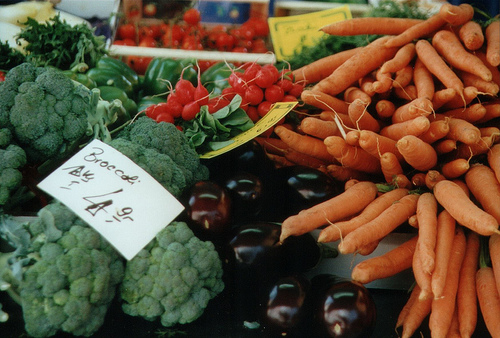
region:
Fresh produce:
[2, 29, 494, 295]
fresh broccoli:
[4, 75, 207, 323]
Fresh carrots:
[309, 24, 499, 239]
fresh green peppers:
[89, 53, 185, 98]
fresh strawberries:
[117, 0, 266, 54]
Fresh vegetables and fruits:
[4, 3, 489, 334]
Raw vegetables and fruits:
[8, 0, 494, 337]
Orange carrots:
[325, 18, 496, 336]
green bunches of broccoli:
[15, 63, 225, 316]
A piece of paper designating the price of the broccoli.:
[29, 120, 199, 275]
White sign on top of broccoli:
[37, 135, 184, 263]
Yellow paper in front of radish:
[199, 92, 301, 167]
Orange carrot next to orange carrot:
[435, 179, 499, 236]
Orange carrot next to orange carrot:
[414, 190, 437, 275]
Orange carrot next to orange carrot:
[270, 179, 379, 243]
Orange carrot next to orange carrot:
[376, 153, 401, 183]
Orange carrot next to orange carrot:
[312, 31, 402, 97]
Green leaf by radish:
[207, 105, 231, 118]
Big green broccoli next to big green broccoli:
[122, 224, 226, 326]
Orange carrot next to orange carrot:
[321, 134, 378, 174]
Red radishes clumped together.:
[146, 58, 310, 122]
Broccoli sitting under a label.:
[0, 62, 227, 330]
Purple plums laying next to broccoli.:
[184, 166, 375, 333]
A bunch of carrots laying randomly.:
[253, 6, 498, 336]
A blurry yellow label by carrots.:
[267, 8, 361, 55]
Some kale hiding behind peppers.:
[16, 10, 107, 80]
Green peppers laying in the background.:
[64, 57, 261, 112]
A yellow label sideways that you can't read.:
[193, 98, 299, 160]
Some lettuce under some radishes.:
[187, 92, 258, 150]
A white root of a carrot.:
[314, 95, 346, 136]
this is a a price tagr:
[27, 140, 163, 253]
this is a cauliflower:
[117, 232, 217, 327]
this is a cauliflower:
[0, 211, 126, 334]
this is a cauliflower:
[92, 115, 192, 196]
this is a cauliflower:
[10, 65, 91, 150]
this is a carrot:
[406, 175, 438, 293]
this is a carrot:
[423, 156, 489, 253]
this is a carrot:
[270, 190, 395, 240]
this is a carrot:
[307, 70, 377, 142]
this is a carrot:
[442, 101, 490, 181]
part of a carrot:
[326, 242, 370, 317]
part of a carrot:
[407, 215, 439, 279]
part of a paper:
[110, 175, 168, 245]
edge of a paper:
[98, 231, 128, 261]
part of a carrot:
[326, 229, 376, 247]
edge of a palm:
[278, 267, 325, 325]